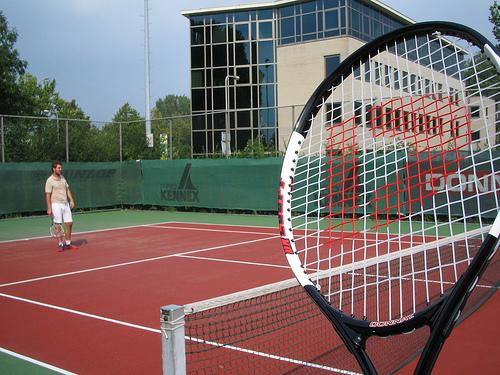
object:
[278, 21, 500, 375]
tennis racket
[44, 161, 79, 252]
man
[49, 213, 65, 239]
tennis racket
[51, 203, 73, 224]
shorts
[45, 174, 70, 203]
shirt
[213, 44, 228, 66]
window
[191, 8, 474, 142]
building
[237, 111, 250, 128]
window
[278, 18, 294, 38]
window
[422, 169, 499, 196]
lettering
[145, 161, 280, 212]
fence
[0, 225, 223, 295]
court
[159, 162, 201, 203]
logo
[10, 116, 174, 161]
fence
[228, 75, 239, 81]
light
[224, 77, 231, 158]
pole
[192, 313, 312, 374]
net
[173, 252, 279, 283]
stripe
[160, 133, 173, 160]
sign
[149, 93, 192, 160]
tree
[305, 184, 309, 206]
string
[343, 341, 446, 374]
handle